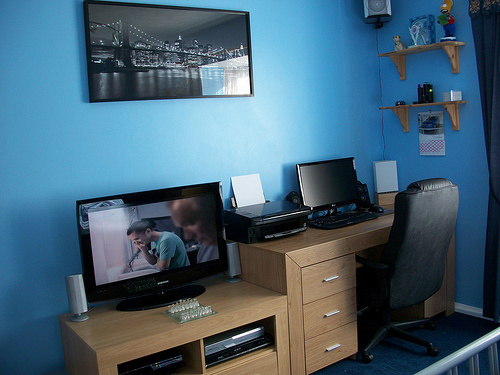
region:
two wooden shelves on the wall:
[375, 22, 467, 137]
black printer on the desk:
[227, 185, 309, 240]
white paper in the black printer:
[234, 168, 268, 210]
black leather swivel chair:
[352, 175, 471, 352]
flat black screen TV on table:
[72, 173, 237, 310]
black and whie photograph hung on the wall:
[66, 1, 266, 115]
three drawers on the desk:
[296, 252, 363, 369]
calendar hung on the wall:
[410, 106, 450, 162]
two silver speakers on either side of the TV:
[60, 242, 247, 322]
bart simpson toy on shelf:
[435, 0, 459, 50]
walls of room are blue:
[0, 0, 487, 372]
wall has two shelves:
[378, 20, 467, 130]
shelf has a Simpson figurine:
[435, 1, 459, 41]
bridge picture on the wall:
[78, 1, 255, 98]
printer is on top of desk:
[224, 195, 309, 241]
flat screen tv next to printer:
[76, 178, 229, 309]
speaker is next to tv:
[65, 273, 93, 324]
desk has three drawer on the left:
[241, 197, 456, 374]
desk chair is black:
[357, 179, 463, 364]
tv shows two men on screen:
[96, 198, 221, 286]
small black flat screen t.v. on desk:
[68, 181, 240, 311]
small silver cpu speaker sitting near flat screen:
[67, 271, 94, 321]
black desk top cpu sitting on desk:
[297, 157, 365, 232]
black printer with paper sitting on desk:
[226, 201, 310, 239]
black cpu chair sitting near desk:
[353, 180, 459, 360]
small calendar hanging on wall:
[416, 111, 448, 156]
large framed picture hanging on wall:
[79, 0, 257, 105]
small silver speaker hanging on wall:
[364, 1, 391, 27]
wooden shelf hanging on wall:
[381, 38, 463, 75]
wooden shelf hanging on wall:
[380, 95, 470, 132]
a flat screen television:
[64, 152, 242, 319]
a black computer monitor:
[288, 149, 388, 224]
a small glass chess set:
[151, 291, 231, 328]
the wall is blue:
[5, 1, 495, 374]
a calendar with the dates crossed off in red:
[412, 108, 464, 165]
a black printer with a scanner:
[220, 174, 321, 257]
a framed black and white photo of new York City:
[69, 1, 276, 106]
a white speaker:
[370, 149, 411, 205]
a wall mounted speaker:
[352, 0, 414, 35]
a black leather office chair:
[353, 164, 491, 367]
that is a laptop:
[82, 175, 213, 320]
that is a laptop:
[241, 186, 298, 233]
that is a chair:
[381, 168, 458, 316]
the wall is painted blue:
[89, 135, 131, 150]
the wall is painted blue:
[282, 97, 346, 124]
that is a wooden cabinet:
[100, 318, 152, 344]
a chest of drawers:
[304, 264, 363, 364]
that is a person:
[130, 220, 180, 267]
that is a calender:
[233, 174, 273, 203]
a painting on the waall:
[89, 9, 243, 90]